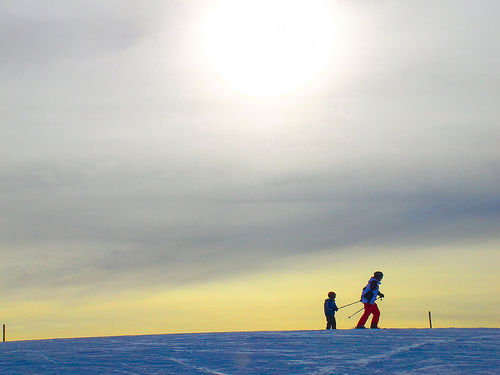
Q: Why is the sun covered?
A: Clouds.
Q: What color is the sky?
A: Grey.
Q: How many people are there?
A: Two.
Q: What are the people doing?
A: Skiing.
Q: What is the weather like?
A: Cold.